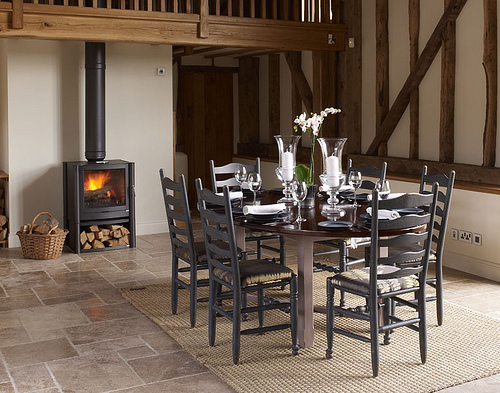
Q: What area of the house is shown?
A: Dining room.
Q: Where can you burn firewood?
A: Furnace.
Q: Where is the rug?
A: Beneath the table.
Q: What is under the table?
A: A tan rug.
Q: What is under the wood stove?
A: Logs.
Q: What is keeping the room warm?
A: A wood stove.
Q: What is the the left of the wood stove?
A: A wicker basket.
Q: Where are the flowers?
A: On the table.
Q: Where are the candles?
A: On the table.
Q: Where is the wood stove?
A: Against the wall.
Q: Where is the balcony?
A: Above the wood stove.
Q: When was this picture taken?
A: Daytime.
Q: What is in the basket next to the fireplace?
A: Wood.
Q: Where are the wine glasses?
A: On the table.